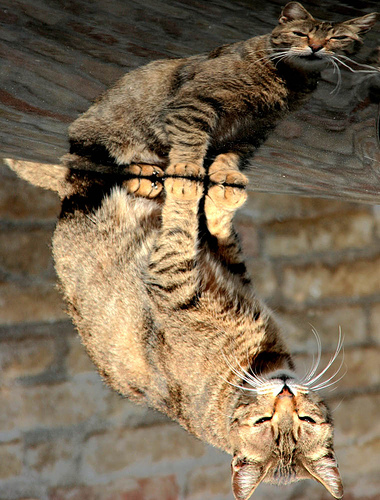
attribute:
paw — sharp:
[121, 154, 259, 182]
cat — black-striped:
[66, 1, 378, 186]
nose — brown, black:
[307, 38, 326, 57]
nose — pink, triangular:
[262, 377, 303, 403]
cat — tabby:
[116, 11, 362, 194]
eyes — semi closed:
[289, 29, 345, 45]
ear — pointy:
[231, 453, 272, 499]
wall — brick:
[5, 178, 379, 499]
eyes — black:
[287, 24, 351, 42]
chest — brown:
[221, 53, 304, 113]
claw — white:
[194, 167, 198, 178]